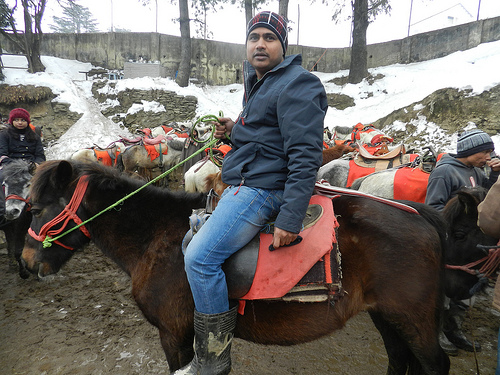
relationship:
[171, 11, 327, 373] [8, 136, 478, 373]
man sitting on horse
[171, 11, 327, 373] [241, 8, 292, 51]
man wearing cap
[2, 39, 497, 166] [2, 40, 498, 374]
snow covering ground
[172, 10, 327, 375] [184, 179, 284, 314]
man wearing jeans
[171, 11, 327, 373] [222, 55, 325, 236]
man wearing coat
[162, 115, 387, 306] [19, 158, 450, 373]
saddle wearing horse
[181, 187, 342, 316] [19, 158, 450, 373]
saddle on horse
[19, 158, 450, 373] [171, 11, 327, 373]
horse carrying man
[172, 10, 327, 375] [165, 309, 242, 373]
man wearing boot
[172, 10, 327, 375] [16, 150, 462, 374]
man on horse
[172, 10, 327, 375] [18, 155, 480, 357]
man sitting on horse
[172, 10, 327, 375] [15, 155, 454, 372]
man riding mule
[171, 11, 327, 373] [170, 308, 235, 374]
man wearing boot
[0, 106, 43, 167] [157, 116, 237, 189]
person riding an animal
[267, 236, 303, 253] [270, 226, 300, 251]
object inside hand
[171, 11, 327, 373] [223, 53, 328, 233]
man wearing a hoodie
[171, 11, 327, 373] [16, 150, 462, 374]
man riding a horse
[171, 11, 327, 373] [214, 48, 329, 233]
man wearing a jacket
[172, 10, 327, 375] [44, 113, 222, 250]
man holding green rope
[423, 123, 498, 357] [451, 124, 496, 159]
man wearing a hat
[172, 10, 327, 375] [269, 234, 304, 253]
man holding sunglasses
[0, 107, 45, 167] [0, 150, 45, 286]
person on top of a horse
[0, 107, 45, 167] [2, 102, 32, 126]
person wearing a cap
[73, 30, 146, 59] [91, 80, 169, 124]
wall on top of a hill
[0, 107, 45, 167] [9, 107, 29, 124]
person wearing a hat